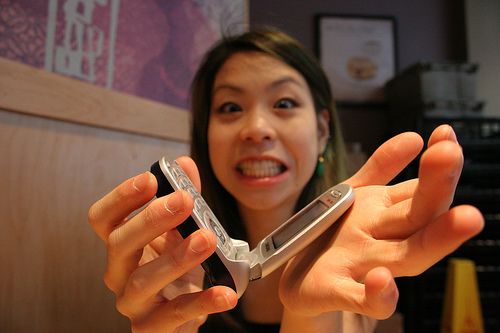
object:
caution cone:
[439, 257, 485, 332]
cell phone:
[149, 156, 355, 299]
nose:
[239, 110, 278, 142]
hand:
[277, 124, 488, 320]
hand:
[85, 154, 236, 333]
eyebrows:
[261, 75, 305, 91]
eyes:
[271, 96, 302, 111]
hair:
[188, 24, 354, 242]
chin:
[240, 194, 283, 211]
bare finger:
[87, 156, 239, 331]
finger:
[337, 122, 487, 319]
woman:
[87, 25, 485, 333]